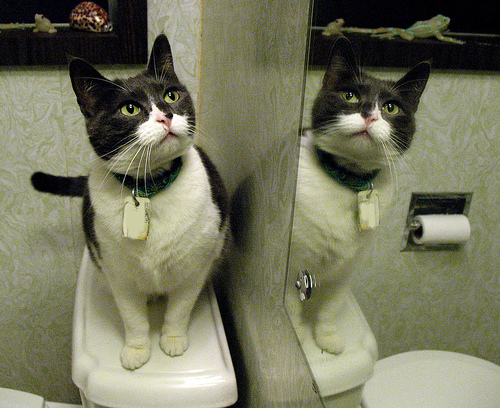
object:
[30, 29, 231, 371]
cat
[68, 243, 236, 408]
toilet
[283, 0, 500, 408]
mirror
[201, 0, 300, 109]
wall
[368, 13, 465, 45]
frog